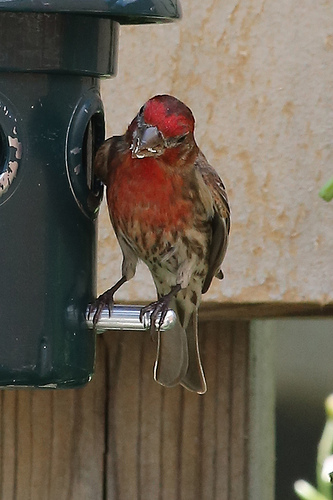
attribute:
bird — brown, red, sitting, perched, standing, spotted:
[84, 94, 228, 393]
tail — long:
[150, 264, 208, 397]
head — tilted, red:
[124, 93, 202, 170]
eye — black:
[135, 105, 149, 120]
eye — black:
[176, 131, 188, 146]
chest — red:
[110, 137, 199, 277]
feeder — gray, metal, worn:
[0, 1, 182, 389]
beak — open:
[130, 112, 179, 164]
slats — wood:
[4, 323, 252, 499]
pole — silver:
[87, 305, 176, 330]